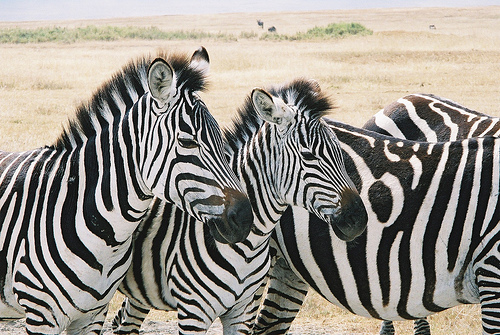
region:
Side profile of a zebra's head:
[105, 29, 261, 247]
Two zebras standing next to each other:
[44, 57, 369, 272]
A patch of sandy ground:
[395, 21, 460, 75]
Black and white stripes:
[401, 168, 490, 258]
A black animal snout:
[325, 190, 371, 248]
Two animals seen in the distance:
[247, 15, 282, 40]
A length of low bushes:
[304, 25, 376, 41]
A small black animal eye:
[296, 143, 321, 162]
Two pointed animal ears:
[140, 42, 215, 104]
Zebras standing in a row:
[0, 45, 497, 334]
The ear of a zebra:
[141, 55, 185, 99]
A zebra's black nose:
[213, 200, 251, 242]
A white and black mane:
[55, 61, 192, 146]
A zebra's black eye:
[179, 127, 201, 150]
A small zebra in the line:
[127, 87, 375, 334]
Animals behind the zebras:
[252, 17, 280, 38]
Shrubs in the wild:
[0, 24, 365, 42]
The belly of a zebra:
[296, 236, 479, 316]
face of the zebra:
[137, 67, 248, 215]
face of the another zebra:
[233, 63, 370, 216]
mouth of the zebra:
[316, 186, 403, 273]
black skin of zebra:
[281, 83, 338, 133]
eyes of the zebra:
[281, 128, 326, 198]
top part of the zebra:
[261, 68, 366, 143]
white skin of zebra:
[418, 168, 461, 314]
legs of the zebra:
[167, 289, 275, 333]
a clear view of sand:
[43, 9, 498, 94]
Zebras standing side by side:
[107, 84, 499, 334]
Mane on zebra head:
[184, 69, 197, 82]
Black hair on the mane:
[103, 83, 110, 89]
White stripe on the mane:
[115, 98, 121, 103]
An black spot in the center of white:
[372, 188, 387, 203]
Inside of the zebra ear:
[258, 96, 268, 112]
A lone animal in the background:
[427, 22, 435, 28]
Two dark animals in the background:
[257, 20, 277, 32]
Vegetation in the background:
[54, 30, 119, 36]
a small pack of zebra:
[0, 45, 499, 334]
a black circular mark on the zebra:
[362, 177, 397, 224]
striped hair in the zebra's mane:
[47, 48, 208, 155]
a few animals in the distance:
[253, 17, 278, 35]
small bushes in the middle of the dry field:
[0, 18, 370, 48]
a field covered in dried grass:
[0, 6, 499, 150]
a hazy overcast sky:
[2, 0, 498, 23]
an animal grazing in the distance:
[427, 20, 437, 30]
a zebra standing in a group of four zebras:
[0, 40, 258, 334]